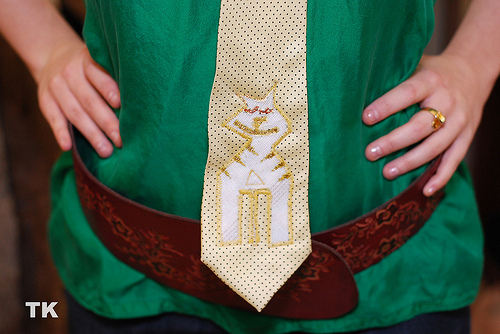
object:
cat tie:
[199, 0, 316, 314]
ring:
[421, 105, 448, 126]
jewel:
[428, 113, 451, 127]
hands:
[21, 38, 137, 160]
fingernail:
[57, 137, 70, 150]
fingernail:
[96, 142, 111, 153]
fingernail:
[109, 132, 121, 143]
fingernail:
[106, 92, 117, 101]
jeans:
[66, 284, 473, 331]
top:
[51, 1, 489, 334]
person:
[2, 1, 499, 332]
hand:
[361, 50, 484, 198]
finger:
[364, 70, 436, 123]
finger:
[364, 105, 446, 159]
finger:
[424, 133, 473, 194]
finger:
[84, 57, 124, 107]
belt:
[69, 130, 447, 314]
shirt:
[44, 0, 485, 334]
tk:
[21, 298, 59, 320]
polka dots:
[199, 0, 313, 313]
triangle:
[243, 169, 267, 189]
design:
[328, 198, 435, 272]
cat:
[218, 82, 293, 247]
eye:
[245, 106, 260, 115]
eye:
[259, 107, 272, 114]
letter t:
[23, 299, 42, 319]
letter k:
[39, 301, 59, 321]